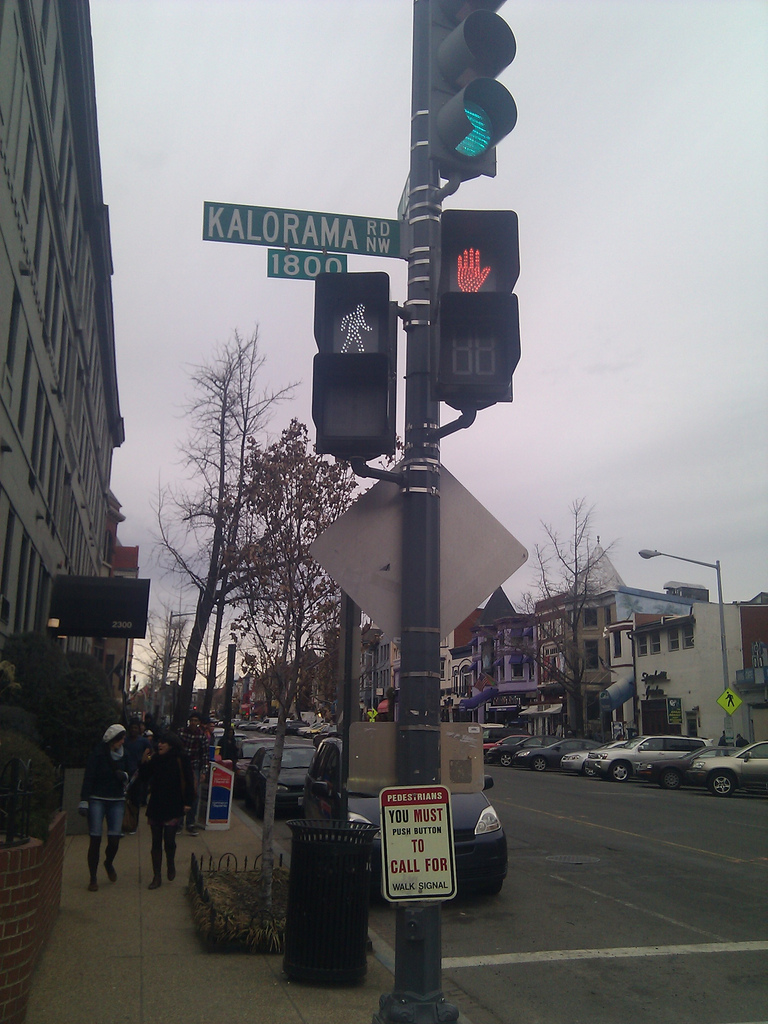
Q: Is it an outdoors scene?
A: Yes, it is outdoors.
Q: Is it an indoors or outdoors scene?
A: It is outdoors.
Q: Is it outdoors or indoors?
A: It is outdoors.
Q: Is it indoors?
A: No, it is outdoors.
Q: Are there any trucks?
A: No, there are no trucks.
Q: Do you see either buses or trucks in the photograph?
A: No, there are no trucks or buses.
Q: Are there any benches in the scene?
A: No, there are no benches.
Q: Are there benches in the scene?
A: No, there are no benches.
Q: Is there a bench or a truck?
A: No, there are no benches or trucks.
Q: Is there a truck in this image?
A: No, there are no trucks.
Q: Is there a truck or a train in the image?
A: No, there are no trucks or trains.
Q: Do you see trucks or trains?
A: No, there are no trucks or trains.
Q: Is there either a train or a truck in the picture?
A: No, there are no trucks or trains.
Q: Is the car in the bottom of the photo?
A: Yes, the car is in the bottom of the image.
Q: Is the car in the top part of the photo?
A: No, the car is in the bottom of the image.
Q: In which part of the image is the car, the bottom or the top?
A: The car is in the bottom of the image.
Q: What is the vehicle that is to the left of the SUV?
A: The vehicle is a car.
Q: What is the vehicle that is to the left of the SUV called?
A: The vehicle is a car.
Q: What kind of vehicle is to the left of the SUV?
A: The vehicle is a car.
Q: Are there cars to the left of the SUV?
A: Yes, there is a car to the left of the SUV.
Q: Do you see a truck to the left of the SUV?
A: No, there is a car to the left of the SUV.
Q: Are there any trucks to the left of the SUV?
A: No, there is a car to the left of the SUV.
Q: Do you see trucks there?
A: No, there are no trucks.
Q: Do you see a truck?
A: No, there are no trucks.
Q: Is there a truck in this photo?
A: No, there are no trucks.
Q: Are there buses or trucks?
A: No, there are no trucks or buses.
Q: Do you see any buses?
A: No, there are no buses.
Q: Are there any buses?
A: No, there are no buses.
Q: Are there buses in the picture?
A: No, there are no buses.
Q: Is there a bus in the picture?
A: No, there are no buses.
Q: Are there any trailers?
A: No, there are no trailers.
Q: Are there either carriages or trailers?
A: No, there are no trailers or carriages.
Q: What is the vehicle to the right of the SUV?
A: The vehicle is a car.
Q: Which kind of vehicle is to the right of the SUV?
A: The vehicle is a car.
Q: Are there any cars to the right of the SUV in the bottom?
A: Yes, there is a car to the right of the SUV.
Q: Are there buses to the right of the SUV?
A: No, there is a car to the right of the SUV.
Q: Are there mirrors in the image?
A: No, there are no mirrors.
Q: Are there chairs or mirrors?
A: No, there are no mirrors or chairs.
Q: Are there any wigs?
A: No, there are no wigs.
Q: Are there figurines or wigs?
A: No, there are no wigs or figurines.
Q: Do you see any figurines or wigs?
A: No, there are no wigs or figurines.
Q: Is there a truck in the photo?
A: No, there are no trucks.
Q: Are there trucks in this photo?
A: No, there are no trucks.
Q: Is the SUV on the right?
A: Yes, the SUV is on the right of the image.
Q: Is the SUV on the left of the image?
A: No, the SUV is on the right of the image.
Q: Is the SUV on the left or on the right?
A: The SUV is on the right of the image.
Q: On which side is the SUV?
A: The SUV is on the right of the image.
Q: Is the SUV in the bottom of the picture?
A: Yes, the SUV is in the bottom of the image.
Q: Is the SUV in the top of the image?
A: No, the SUV is in the bottom of the image.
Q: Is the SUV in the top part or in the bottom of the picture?
A: The SUV is in the bottom of the image.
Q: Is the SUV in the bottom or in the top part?
A: The SUV is in the bottom of the image.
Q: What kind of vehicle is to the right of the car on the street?
A: The vehicle is a SUV.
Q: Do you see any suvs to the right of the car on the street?
A: Yes, there is a SUV to the right of the car.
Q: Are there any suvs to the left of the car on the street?
A: No, the SUV is to the right of the car.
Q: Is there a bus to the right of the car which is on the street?
A: No, there is a SUV to the right of the car.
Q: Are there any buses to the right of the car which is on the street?
A: No, there is a SUV to the right of the car.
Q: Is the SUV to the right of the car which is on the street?
A: Yes, the SUV is to the right of the car.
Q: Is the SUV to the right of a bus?
A: No, the SUV is to the right of the car.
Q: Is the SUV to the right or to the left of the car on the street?
A: The SUV is to the right of the car.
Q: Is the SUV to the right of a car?
A: Yes, the SUV is to the right of a car.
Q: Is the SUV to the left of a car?
A: Yes, the SUV is to the left of a car.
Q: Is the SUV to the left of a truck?
A: No, the SUV is to the left of a car.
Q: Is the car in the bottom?
A: Yes, the car is in the bottom of the image.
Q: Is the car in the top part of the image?
A: No, the car is in the bottom of the image.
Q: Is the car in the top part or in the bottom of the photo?
A: The car is in the bottom of the image.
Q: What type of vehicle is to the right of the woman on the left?
A: The vehicle is a car.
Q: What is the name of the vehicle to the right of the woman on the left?
A: The vehicle is a car.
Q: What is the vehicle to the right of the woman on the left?
A: The vehicle is a car.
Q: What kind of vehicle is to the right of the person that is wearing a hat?
A: The vehicle is a car.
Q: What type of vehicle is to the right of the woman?
A: The vehicle is a car.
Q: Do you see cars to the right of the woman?
A: Yes, there is a car to the right of the woman.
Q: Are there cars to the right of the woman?
A: Yes, there is a car to the right of the woman.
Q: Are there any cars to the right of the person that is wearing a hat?
A: Yes, there is a car to the right of the woman.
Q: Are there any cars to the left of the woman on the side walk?
A: No, the car is to the right of the woman.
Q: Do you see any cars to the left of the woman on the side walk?
A: No, the car is to the right of the woman.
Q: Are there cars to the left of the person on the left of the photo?
A: No, the car is to the right of the woman.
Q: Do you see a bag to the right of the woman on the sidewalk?
A: No, there is a car to the right of the woman.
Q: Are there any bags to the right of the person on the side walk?
A: No, there is a car to the right of the woman.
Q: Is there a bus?
A: No, there are no buses.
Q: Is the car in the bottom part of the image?
A: Yes, the car is in the bottom of the image.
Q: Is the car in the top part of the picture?
A: No, the car is in the bottom of the image.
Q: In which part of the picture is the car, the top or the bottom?
A: The car is in the bottom of the image.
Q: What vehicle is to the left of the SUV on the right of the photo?
A: The vehicle is a car.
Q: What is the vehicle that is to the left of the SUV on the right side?
A: The vehicle is a car.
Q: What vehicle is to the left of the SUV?
A: The vehicle is a car.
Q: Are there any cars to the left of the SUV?
A: Yes, there is a car to the left of the SUV.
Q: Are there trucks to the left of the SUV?
A: No, there is a car to the left of the SUV.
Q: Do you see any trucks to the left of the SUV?
A: No, there is a car to the left of the SUV.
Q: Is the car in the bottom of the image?
A: Yes, the car is in the bottom of the image.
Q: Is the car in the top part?
A: No, the car is in the bottom of the image.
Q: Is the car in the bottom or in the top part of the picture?
A: The car is in the bottom of the image.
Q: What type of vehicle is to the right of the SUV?
A: The vehicle is a car.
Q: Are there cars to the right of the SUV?
A: Yes, there is a car to the right of the SUV.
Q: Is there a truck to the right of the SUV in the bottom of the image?
A: No, there is a car to the right of the SUV.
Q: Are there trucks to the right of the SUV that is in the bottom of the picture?
A: No, there is a car to the right of the SUV.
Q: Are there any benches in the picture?
A: No, there are no benches.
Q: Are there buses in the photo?
A: No, there are no buses.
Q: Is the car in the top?
A: No, the car is in the bottom of the image.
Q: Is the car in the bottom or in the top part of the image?
A: The car is in the bottom of the image.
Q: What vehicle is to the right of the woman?
A: The vehicle is a car.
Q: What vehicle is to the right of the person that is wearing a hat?
A: The vehicle is a car.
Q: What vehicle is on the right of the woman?
A: The vehicle is a car.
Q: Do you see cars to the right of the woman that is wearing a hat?
A: Yes, there is a car to the right of the woman.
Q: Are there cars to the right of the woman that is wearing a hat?
A: Yes, there is a car to the right of the woman.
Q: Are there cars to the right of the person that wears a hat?
A: Yes, there is a car to the right of the woman.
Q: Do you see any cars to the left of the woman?
A: No, the car is to the right of the woman.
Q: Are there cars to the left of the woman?
A: No, the car is to the right of the woman.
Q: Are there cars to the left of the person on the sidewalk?
A: No, the car is to the right of the woman.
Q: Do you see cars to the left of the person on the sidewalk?
A: No, the car is to the right of the woman.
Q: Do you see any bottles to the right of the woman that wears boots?
A: No, there is a car to the right of the woman.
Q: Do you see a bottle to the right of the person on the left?
A: No, there is a car to the right of the woman.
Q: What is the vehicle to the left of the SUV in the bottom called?
A: The vehicle is a car.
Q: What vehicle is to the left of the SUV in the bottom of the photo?
A: The vehicle is a car.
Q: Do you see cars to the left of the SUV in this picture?
A: Yes, there is a car to the left of the SUV.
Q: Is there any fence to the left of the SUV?
A: No, there is a car to the left of the SUV.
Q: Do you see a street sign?
A: Yes, there is a street sign.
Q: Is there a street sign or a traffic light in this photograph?
A: Yes, there is a street sign.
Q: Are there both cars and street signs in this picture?
A: Yes, there are both a street sign and a car.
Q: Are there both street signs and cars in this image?
A: Yes, there are both a street sign and a car.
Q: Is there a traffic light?
A: Yes, there is a traffic light.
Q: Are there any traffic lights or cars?
A: Yes, there is a traffic light.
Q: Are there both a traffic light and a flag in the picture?
A: No, there is a traffic light but no flags.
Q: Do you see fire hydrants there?
A: No, there are no fire hydrants.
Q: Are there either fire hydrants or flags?
A: No, there are no fire hydrants or flags.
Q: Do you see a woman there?
A: Yes, there is a woman.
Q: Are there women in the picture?
A: Yes, there is a woman.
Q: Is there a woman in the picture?
A: Yes, there is a woman.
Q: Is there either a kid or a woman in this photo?
A: Yes, there is a woman.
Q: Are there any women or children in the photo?
A: Yes, there is a woman.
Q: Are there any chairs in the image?
A: No, there are no chairs.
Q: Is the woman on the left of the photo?
A: Yes, the woman is on the left of the image.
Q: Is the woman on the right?
A: No, the woman is on the left of the image.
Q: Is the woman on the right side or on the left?
A: The woman is on the left of the image.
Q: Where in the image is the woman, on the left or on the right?
A: The woman is on the left of the image.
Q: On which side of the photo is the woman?
A: The woman is on the left of the image.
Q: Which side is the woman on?
A: The woman is on the left of the image.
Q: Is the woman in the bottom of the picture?
A: Yes, the woman is in the bottom of the image.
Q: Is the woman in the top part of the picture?
A: No, the woman is in the bottom of the image.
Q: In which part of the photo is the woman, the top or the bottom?
A: The woman is in the bottom of the image.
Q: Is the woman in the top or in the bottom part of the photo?
A: The woman is in the bottom of the image.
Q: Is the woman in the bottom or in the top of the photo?
A: The woman is in the bottom of the image.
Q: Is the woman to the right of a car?
A: No, the woman is to the left of a car.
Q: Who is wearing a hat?
A: The woman is wearing a hat.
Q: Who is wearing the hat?
A: The woman is wearing a hat.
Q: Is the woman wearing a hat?
A: Yes, the woman is wearing a hat.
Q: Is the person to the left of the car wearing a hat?
A: Yes, the woman is wearing a hat.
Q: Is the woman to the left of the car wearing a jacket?
A: No, the woman is wearing a hat.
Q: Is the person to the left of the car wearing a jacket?
A: No, the woman is wearing a hat.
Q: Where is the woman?
A: The woman is on the sidewalk.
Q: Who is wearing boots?
A: The woman is wearing boots.